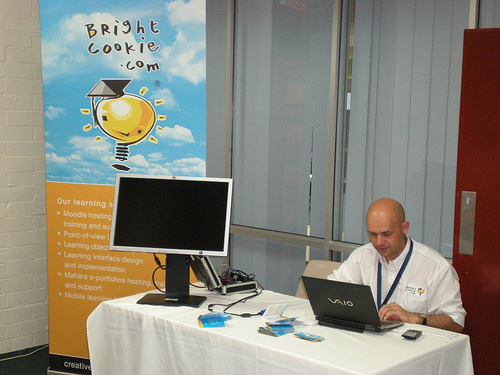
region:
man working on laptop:
[293, 183, 462, 342]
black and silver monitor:
[115, 163, 240, 305]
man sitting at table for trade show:
[43, 3, 483, 373]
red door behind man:
[438, 13, 498, 364]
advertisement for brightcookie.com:
[55, 5, 191, 179]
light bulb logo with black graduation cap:
[62, 67, 177, 179]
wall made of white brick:
[3, 21, 35, 326]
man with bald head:
[353, 186, 435, 273]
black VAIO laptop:
[292, 266, 407, 331]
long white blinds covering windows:
[256, 13, 430, 217]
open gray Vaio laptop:
[298, 275, 397, 339]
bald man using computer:
[313, 193, 480, 338]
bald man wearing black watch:
[318, 185, 475, 330]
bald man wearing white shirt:
[306, 201, 465, 331]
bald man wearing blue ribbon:
[313, 193, 478, 338]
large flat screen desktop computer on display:
[103, 179, 243, 317]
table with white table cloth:
[88, 268, 482, 373]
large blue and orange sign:
[36, 0, 218, 372]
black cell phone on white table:
[400, 325, 422, 343]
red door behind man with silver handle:
[449, 22, 499, 373]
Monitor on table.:
[115, 142, 301, 340]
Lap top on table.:
[295, 239, 483, 350]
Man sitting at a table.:
[304, 189, 468, 359]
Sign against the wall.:
[50, 108, 271, 290]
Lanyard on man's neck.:
[341, 237, 450, 346]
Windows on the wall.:
[206, 5, 463, 296]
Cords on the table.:
[218, 260, 308, 355]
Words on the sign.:
[65, 30, 206, 175]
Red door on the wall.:
[429, 137, 492, 269]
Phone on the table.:
[400, 317, 445, 366]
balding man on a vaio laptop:
[314, 197, 457, 337]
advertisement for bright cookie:
[76, 22, 174, 162]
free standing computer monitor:
[105, 152, 247, 305]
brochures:
[233, 314, 317, 354]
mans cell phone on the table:
[402, 321, 427, 353]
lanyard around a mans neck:
[366, 240, 418, 321]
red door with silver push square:
[463, 37, 490, 334]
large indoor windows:
[197, 2, 332, 256]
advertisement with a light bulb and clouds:
[37, 12, 205, 176]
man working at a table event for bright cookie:
[85, 143, 480, 370]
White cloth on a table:
[104, 273, 407, 370]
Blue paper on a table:
[256, 305, 331, 347]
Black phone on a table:
[401, 320, 428, 349]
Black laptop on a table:
[298, 265, 395, 325]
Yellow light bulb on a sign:
[70, 93, 187, 155]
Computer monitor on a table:
[107, 169, 271, 348]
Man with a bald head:
[356, 183, 463, 310]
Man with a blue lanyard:
[358, 192, 402, 300]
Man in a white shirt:
[321, 181, 498, 320]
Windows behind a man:
[224, 89, 437, 262]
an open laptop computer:
[301, 274, 401, 332]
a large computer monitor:
[110, 170, 235, 304]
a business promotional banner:
[40, 0, 209, 370]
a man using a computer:
[300, 196, 466, 332]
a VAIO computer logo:
[325, 295, 353, 307]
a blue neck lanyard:
[375, 235, 415, 310]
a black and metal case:
[190, 252, 259, 292]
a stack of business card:
[258, 320, 292, 335]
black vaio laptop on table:
[288, 268, 405, 339]